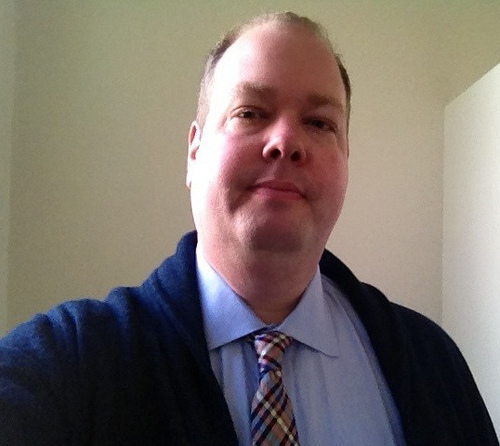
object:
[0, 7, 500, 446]
person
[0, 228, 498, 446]
sweater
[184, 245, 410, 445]
shirt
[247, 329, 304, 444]
tie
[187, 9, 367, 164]
hair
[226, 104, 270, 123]
eyes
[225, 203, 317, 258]
chin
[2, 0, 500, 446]
wall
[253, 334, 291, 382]
knot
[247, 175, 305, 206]
mouth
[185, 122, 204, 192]
ear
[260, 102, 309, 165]
nose